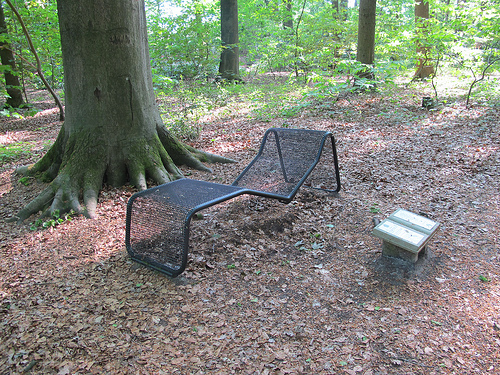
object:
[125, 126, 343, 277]
bench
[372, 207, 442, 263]
statue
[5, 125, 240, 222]
tree roots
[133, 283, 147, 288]
leaves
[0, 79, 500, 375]
ground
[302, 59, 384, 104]
vegetation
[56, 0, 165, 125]
tree trunk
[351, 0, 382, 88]
tree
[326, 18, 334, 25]
leaves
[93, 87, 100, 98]
notch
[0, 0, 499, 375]
forest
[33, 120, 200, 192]
moss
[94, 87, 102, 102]
hole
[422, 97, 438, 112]
sign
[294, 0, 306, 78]
branches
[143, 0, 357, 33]
sky